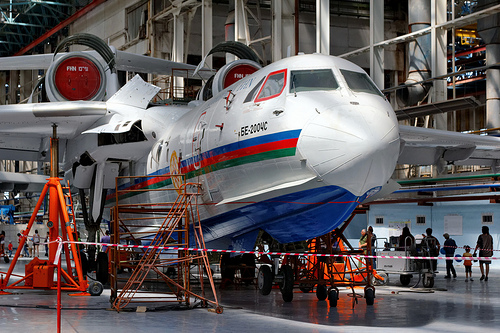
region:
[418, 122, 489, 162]
the wing on the airplane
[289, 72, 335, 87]
a windshield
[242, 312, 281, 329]
the ground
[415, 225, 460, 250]
people standing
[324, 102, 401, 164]
the nose of the plane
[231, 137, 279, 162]
color on the plane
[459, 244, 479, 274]
a child standing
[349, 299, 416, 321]
a shadow under the plane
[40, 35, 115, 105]
Red engine of the plane.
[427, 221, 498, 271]
People standing by the plane.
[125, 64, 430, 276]
The plane is on display.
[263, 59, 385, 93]
Cockpit of the plane.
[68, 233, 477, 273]
The plane is roped off.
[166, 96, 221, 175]
The door on the airplane.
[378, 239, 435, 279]
A cart by the plane.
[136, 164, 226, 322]
A portable stair case next to the plane.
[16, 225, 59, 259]
People walking in the building.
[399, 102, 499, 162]
The wing of the plane.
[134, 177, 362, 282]
blue bottom of the airplane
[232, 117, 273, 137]
black numbers and letters on the white plane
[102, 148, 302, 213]
green stripe on the white airplane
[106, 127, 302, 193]
blue stripe on the white airplane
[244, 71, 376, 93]
windows on the cockpit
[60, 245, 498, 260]
red and white striped rope around the airplane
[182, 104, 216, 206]
door on the side of the airplane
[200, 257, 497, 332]
shadow of the airplane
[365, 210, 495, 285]
people walking around the airplane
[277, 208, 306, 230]
the plane is blue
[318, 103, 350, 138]
the plane is white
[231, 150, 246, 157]
the plane is red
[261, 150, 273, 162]
the plane is green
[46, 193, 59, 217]
the pole is orange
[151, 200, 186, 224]
the lift is brown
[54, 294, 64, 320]
the pole is red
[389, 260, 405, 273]
the cart is gray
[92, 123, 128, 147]
the door is open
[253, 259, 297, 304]
the tires are offf the ground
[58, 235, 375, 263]
A red and white cross line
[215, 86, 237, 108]
A small handle bars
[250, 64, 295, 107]
A red border around the window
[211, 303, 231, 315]
Small wheel of the ladder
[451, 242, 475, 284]
A kid holding a blue balloon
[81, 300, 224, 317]
Black wires are on the floor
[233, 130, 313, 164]
A blu, red and green lines at the side of the plane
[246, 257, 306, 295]
A pair of wheels in front of the plane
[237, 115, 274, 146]
Black marking at the top of the colored lines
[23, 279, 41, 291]
Tip of an orange box